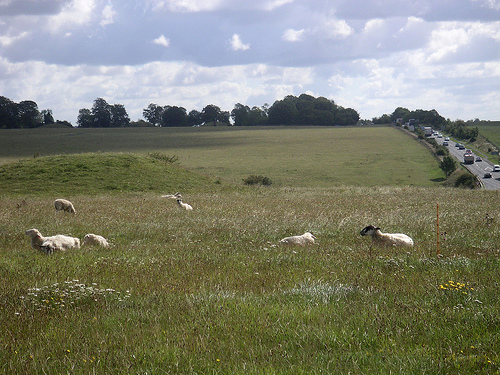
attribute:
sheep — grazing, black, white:
[22, 217, 91, 267]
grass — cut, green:
[139, 227, 260, 333]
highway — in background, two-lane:
[373, 111, 495, 195]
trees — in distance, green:
[2, 103, 346, 133]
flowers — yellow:
[434, 262, 468, 299]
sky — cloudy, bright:
[34, 4, 456, 91]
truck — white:
[464, 146, 480, 172]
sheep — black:
[352, 208, 425, 273]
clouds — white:
[154, 5, 472, 64]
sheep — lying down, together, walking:
[31, 174, 415, 280]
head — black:
[361, 213, 385, 235]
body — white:
[376, 230, 427, 252]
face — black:
[351, 232, 375, 240]